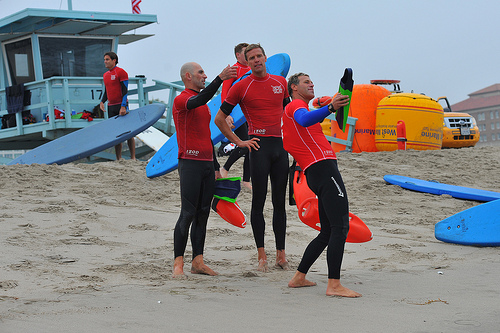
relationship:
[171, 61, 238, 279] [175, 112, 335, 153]
lifeguards wearing tops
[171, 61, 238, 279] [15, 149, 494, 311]
lifeguards on beach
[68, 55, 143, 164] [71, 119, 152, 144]
man holds board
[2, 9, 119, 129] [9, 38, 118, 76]
building has windows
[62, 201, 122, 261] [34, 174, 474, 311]
footprints in sand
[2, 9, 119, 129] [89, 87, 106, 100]
building has number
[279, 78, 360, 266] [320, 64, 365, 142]
man holding object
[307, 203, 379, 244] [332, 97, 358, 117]
float in hand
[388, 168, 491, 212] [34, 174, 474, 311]
surfboard on sand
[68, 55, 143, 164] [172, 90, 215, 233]
man wearing wetsuit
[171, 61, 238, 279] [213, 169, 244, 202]
lifeguards holding shoe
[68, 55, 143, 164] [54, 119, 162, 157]
man holding surfboard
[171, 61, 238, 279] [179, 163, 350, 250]
lifeguards wearing pants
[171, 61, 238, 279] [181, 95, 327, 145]
lifeguards wearing shirts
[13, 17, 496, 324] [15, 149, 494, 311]
picture at beach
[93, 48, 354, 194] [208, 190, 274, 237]
lifeguards holdind life perservers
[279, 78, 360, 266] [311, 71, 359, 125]
man holding flipper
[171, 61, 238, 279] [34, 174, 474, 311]
lifeguards on sand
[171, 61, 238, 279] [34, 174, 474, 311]
lifeguards standing in sand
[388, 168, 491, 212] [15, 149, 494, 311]
surfboard on beach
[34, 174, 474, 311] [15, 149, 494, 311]
sand on beach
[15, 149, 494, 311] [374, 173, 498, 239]
beach has surfboards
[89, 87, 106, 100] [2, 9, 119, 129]
number on building